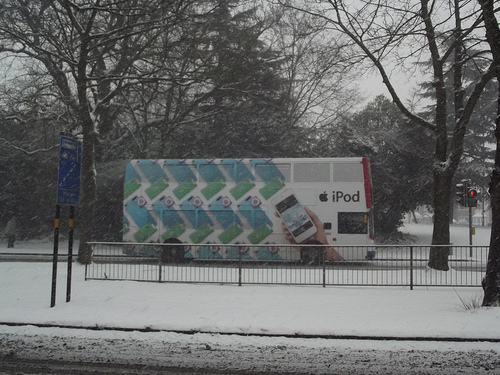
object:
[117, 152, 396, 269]
bus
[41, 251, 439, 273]
road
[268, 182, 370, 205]
advertisement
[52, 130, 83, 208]
sign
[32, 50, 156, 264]
trees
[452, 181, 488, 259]
traffic light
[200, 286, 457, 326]
snow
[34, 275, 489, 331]
ground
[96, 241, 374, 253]
railing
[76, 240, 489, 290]
fence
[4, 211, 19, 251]
man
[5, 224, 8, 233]
device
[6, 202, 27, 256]
person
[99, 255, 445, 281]
sidewalk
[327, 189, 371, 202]
ipod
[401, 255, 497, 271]
street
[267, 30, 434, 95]
sky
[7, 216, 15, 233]
jacket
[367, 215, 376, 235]
windshield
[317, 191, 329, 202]
logo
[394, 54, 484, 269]
tree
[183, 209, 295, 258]
gate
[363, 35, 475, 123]
branches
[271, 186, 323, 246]
cellphon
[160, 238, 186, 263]
wheel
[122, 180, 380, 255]
vehicle